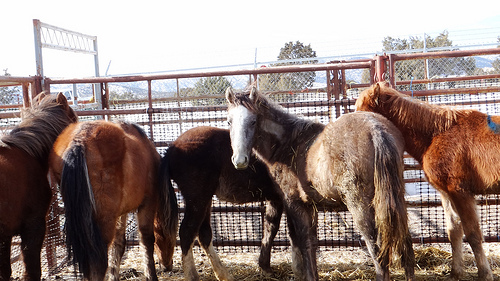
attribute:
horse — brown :
[353, 76, 498, 279]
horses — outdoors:
[3, 86, 490, 278]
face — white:
[227, 107, 257, 168]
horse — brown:
[216, 83, 418, 275]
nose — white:
[228, 151, 246, 163]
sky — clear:
[309, 7, 422, 25]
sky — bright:
[46, 12, 491, 91]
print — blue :
[475, 105, 497, 143]